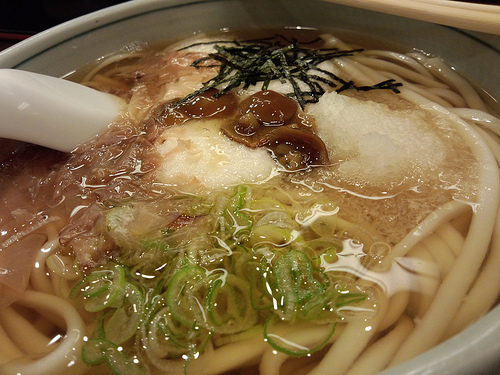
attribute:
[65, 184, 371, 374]
vegetables — green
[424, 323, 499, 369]
bowl — grey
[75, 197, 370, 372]
food — green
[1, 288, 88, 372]
onion — semi-circled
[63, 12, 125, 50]
trim — blue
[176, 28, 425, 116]
food — black, stringy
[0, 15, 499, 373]
soup — Asian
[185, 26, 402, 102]
spices — green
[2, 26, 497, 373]
food — liquid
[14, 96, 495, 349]
broth — clear